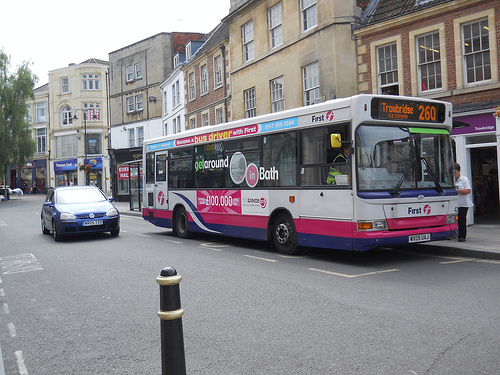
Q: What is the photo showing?
A: It is showing a road.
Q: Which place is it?
A: It is a road.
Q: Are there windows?
A: Yes, there is a window.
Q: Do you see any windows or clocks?
A: Yes, there is a window.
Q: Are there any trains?
A: No, there are no trains.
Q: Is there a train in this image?
A: No, there are no trains.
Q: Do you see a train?
A: No, there are no trains.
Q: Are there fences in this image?
A: No, there are no fences.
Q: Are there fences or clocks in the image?
A: No, there are no fences or clocks.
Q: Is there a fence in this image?
A: No, there are no fences.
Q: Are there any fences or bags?
A: No, there are no fences or bags.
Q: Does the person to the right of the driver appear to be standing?
A: Yes, the person is standing.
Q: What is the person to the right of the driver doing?
A: The person is standing.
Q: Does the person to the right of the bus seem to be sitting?
A: No, the person is standing.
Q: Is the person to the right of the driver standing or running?
A: The person is standing.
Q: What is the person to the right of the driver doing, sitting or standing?
A: The person is standing.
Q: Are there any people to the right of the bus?
A: Yes, there is a person to the right of the bus.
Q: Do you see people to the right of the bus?
A: Yes, there is a person to the right of the bus.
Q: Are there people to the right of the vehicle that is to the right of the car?
A: Yes, there is a person to the right of the bus.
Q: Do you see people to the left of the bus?
A: No, the person is to the right of the bus.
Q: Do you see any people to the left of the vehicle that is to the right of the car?
A: No, the person is to the right of the bus.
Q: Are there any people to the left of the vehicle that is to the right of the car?
A: No, the person is to the right of the bus.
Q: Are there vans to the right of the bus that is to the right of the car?
A: No, there is a person to the right of the bus.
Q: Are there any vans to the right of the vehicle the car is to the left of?
A: No, there is a person to the right of the bus.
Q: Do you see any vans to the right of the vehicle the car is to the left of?
A: No, there is a person to the right of the bus.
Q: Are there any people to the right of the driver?
A: Yes, there is a person to the right of the driver.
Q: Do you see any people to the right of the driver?
A: Yes, there is a person to the right of the driver.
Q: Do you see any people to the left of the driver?
A: No, the person is to the right of the driver.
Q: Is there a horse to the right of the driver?
A: No, there is a person to the right of the driver.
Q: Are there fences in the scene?
A: No, there are no fences.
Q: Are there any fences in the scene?
A: No, there are no fences.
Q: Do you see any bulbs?
A: No, there are no bulbs.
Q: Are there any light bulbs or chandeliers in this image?
A: No, there are no light bulbs or chandeliers.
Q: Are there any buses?
A: Yes, there is a bus.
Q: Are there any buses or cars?
A: Yes, there is a bus.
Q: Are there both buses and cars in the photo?
A: Yes, there are both a bus and a car.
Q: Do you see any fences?
A: No, there are no fences.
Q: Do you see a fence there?
A: No, there are no fences.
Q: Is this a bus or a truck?
A: This is a bus.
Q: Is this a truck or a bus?
A: This is a bus.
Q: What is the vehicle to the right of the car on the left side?
A: The vehicle is a bus.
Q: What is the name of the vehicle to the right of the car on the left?
A: The vehicle is a bus.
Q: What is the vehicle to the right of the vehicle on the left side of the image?
A: The vehicle is a bus.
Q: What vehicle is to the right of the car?
A: The vehicle is a bus.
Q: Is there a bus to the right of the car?
A: Yes, there is a bus to the right of the car.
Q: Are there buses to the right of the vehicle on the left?
A: Yes, there is a bus to the right of the car.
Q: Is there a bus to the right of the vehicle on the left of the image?
A: Yes, there is a bus to the right of the car.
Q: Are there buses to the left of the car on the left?
A: No, the bus is to the right of the car.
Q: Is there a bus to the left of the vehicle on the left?
A: No, the bus is to the right of the car.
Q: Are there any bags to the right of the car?
A: No, there is a bus to the right of the car.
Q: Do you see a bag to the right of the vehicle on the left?
A: No, there is a bus to the right of the car.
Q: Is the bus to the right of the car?
A: Yes, the bus is to the right of the car.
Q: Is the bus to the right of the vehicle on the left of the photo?
A: Yes, the bus is to the right of the car.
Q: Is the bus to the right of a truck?
A: No, the bus is to the right of the car.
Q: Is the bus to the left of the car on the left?
A: No, the bus is to the right of the car.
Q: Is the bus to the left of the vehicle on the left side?
A: No, the bus is to the right of the car.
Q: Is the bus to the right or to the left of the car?
A: The bus is to the right of the car.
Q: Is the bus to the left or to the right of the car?
A: The bus is to the right of the car.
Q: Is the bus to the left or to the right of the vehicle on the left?
A: The bus is to the right of the car.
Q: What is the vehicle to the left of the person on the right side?
A: The vehicle is a bus.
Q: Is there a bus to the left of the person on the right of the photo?
A: Yes, there is a bus to the left of the person.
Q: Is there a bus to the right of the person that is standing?
A: No, the bus is to the left of the person.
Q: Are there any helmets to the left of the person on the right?
A: No, there is a bus to the left of the person.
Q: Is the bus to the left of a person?
A: Yes, the bus is to the left of a person.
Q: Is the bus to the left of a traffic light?
A: No, the bus is to the left of a person.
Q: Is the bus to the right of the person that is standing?
A: No, the bus is to the left of the person.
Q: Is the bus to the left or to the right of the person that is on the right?
A: The bus is to the left of the person.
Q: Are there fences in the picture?
A: No, there are no fences.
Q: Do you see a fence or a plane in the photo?
A: No, there are no fences or airplanes.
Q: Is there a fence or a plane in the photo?
A: No, there are no fences or airplanes.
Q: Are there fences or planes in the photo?
A: No, there are no fences or planes.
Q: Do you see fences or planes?
A: No, there are no fences or planes.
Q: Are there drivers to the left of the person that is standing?
A: Yes, there is a driver to the left of the person.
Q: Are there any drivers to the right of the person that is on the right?
A: No, the driver is to the left of the person.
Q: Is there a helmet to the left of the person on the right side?
A: No, there is a driver to the left of the person.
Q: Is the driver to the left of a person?
A: Yes, the driver is to the left of a person.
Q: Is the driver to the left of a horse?
A: No, the driver is to the left of a person.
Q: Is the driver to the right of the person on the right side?
A: No, the driver is to the left of the person.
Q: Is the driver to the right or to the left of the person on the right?
A: The driver is to the left of the person.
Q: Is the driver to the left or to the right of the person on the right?
A: The driver is to the left of the person.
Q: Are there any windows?
A: Yes, there are windows.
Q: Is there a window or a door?
A: Yes, there are windows.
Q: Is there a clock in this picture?
A: No, there are no clocks.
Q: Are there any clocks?
A: No, there are no clocks.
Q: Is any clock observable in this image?
A: No, there are no clocks.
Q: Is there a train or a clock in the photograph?
A: No, there are no clocks or trains.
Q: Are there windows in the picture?
A: Yes, there is a window.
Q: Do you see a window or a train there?
A: Yes, there is a window.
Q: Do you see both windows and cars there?
A: Yes, there are both a window and a car.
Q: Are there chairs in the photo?
A: No, there are no chairs.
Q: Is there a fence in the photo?
A: No, there are no fences.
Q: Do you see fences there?
A: No, there are no fences.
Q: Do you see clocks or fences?
A: No, there are no fences or clocks.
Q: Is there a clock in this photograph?
A: No, there are no clocks.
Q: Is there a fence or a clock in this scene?
A: No, there are no clocks or fences.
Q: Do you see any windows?
A: Yes, there is a window.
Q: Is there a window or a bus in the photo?
A: Yes, there is a window.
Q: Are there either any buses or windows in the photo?
A: Yes, there is a window.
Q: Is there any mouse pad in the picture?
A: No, there are no mouse pads.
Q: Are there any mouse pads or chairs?
A: No, there are no mouse pads or chairs.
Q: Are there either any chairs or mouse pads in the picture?
A: No, there are no mouse pads or chairs.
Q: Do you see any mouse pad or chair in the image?
A: No, there are no mouse pads or chairs.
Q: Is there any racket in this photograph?
A: No, there are no rackets.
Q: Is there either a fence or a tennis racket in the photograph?
A: No, there are no rackets or fences.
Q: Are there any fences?
A: No, there are no fences.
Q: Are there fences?
A: No, there are no fences.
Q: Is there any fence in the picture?
A: No, there are no fences.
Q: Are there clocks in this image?
A: No, there are no clocks.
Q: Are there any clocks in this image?
A: No, there are no clocks.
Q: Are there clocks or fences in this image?
A: No, there are no clocks or fences.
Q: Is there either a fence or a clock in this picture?
A: No, there are no clocks or fences.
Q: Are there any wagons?
A: No, there are no wagons.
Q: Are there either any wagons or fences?
A: No, there are no wagons or fences.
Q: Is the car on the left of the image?
A: Yes, the car is on the left of the image.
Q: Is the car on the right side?
A: No, the car is on the left of the image.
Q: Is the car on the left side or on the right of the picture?
A: The car is on the left of the image.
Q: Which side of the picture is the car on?
A: The car is on the left of the image.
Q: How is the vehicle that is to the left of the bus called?
A: The vehicle is a car.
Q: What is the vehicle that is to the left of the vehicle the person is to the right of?
A: The vehicle is a car.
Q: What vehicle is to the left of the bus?
A: The vehicle is a car.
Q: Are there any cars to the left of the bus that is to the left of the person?
A: Yes, there is a car to the left of the bus.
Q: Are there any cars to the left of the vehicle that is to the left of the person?
A: Yes, there is a car to the left of the bus.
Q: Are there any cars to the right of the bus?
A: No, the car is to the left of the bus.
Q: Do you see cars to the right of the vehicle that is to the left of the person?
A: No, the car is to the left of the bus.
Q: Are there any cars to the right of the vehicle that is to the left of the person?
A: No, the car is to the left of the bus.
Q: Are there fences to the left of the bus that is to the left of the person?
A: No, there is a car to the left of the bus.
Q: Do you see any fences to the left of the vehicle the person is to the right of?
A: No, there is a car to the left of the bus.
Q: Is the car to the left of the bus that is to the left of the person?
A: Yes, the car is to the left of the bus.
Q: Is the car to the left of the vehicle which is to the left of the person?
A: Yes, the car is to the left of the bus.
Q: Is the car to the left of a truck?
A: No, the car is to the left of the bus.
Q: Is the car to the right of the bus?
A: No, the car is to the left of the bus.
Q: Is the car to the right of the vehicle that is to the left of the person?
A: No, the car is to the left of the bus.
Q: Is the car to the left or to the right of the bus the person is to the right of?
A: The car is to the left of the bus.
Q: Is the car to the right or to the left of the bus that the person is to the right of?
A: The car is to the left of the bus.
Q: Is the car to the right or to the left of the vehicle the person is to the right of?
A: The car is to the left of the bus.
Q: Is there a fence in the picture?
A: No, there are no fences.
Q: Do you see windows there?
A: Yes, there is a window.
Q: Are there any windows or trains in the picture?
A: Yes, there is a window.